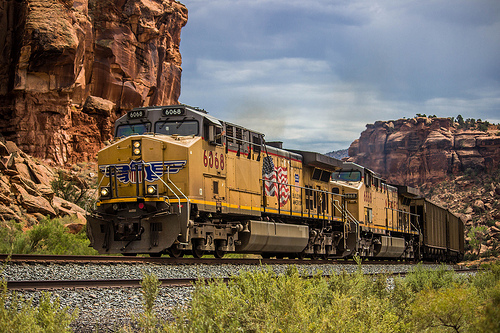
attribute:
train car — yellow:
[334, 165, 419, 265]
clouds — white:
[197, 13, 347, 111]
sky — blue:
[178, 3, 499, 163]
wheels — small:
[145, 240, 305, 262]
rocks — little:
[168, 293, 175, 300]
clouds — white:
[257, 60, 297, 121]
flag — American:
[259, 159, 307, 209]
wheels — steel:
[153, 213, 277, 260]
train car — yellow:
[92, 103, 337, 260]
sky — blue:
[171, 0, 498, 150]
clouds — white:
[187, 6, 364, 122]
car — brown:
[421, 193, 466, 262]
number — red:
[202, 147, 227, 170]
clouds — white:
[343, 2, 493, 97]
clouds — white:
[206, 61, 302, 81]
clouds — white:
[278, 118, 337, 141]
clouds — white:
[451, 96, 496, 110]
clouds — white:
[209, 6, 294, 36]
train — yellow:
[86, 97, 466, 266]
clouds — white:
[202, 46, 378, 120]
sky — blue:
[213, 16, 378, 132]